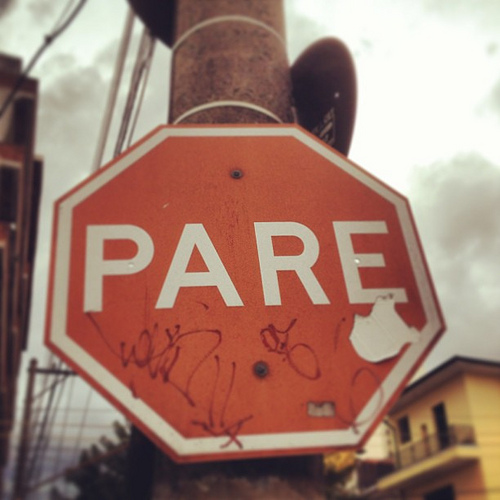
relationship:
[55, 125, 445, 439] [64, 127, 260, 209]
sign has borders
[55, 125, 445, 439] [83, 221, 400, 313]
sign has letters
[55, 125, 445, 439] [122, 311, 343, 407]
sign has graffiti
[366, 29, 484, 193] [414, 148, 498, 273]
sky has clouds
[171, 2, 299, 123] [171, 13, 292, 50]
pole has circles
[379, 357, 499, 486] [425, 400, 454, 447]
building has door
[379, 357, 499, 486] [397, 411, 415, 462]
building has windows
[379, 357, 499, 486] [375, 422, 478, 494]
building has balcony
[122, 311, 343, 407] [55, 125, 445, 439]
graffiti on sign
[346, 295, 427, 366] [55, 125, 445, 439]
spot on sign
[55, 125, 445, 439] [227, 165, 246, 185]
sign has screw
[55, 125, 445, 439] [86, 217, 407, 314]
sign has pare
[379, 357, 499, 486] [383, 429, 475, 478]
building has balcony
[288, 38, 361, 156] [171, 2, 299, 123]
sign on pole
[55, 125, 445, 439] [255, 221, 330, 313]
sign has r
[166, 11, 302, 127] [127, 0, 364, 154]
straps holding signs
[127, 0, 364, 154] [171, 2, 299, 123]
signs on pole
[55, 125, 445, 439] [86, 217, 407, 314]
sign says pare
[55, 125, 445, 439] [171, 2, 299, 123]
sign on pole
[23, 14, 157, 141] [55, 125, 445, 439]
lines above sign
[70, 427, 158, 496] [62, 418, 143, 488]
trees on background